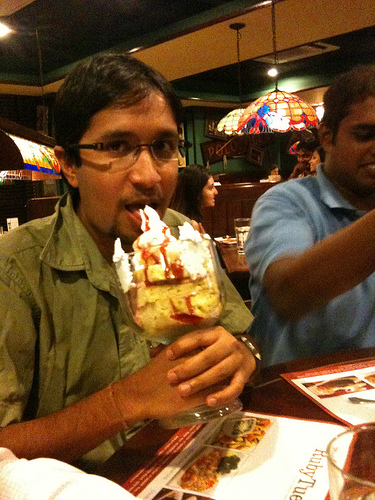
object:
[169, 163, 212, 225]
hair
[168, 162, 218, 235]
woman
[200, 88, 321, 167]
decorations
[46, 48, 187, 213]
hair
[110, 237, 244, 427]
glass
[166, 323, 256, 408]
hand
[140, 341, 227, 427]
hand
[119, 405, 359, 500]
paper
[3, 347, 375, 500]
table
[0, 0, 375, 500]
restaurant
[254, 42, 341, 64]
vent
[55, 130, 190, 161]
glasses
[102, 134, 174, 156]
eye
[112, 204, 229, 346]
cake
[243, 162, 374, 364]
blue shirt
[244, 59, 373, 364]
friend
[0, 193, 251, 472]
shirt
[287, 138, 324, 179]
friends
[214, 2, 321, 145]
lamp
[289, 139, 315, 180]
boy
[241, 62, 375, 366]
boy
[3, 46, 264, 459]
boy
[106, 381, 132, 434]
bracelet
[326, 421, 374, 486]
cup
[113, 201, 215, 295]
whipped cream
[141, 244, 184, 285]
syrup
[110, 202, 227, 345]
ice cream